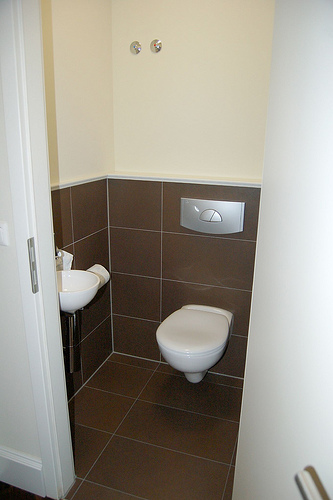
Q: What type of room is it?
A: It is a bathroom.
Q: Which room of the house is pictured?
A: It is a bathroom.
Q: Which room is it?
A: It is a bathroom.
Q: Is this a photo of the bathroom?
A: Yes, it is showing the bathroom.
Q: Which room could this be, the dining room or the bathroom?
A: It is the bathroom.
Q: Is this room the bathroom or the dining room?
A: It is the bathroom.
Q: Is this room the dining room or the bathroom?
A: It is the bathroom.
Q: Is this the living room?
A: No, it is the bathroom.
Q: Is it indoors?
A: Yes, it is indoors.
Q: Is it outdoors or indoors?
A: It is indoors.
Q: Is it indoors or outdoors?
A: It is indoors.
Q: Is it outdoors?
A: No, it is indoors.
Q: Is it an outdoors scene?
A: No, it is indoors.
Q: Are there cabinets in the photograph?
A: No, there are no cabinets.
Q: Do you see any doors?
A: Yes, there is a door.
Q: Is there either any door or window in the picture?
A: Yes, there is a door.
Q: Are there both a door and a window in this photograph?
A: No, there is a door but no windows.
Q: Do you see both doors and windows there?
A: No, there is a door but no windows.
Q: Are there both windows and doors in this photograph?
A: No, there is a door but no windows.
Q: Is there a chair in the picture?
A: No, there are no chairs.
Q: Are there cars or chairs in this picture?
A: No, there are no chairs or cars.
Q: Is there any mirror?
A: No, there are no mirrors.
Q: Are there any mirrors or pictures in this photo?
A: No, there are no mirrors or pictures.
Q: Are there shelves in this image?
A: No, there are no shelves.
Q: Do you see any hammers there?
A: No, there are no hammers.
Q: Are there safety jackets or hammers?
A: No, there are no hammers or safety jackets.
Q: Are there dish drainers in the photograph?
A: No, there are no dish drainers.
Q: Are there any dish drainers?
A: No, there are no dish drainers.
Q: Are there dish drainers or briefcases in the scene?
A: No, there are no dish drainers or briefcases.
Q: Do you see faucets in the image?
A: No, there are no faucets.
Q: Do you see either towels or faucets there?
A: No, there are no faucets or towels.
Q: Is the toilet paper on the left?
A: Yes, the toilet paper is on the left of the image.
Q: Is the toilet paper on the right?
A: No, the toilet paper is on the left of the image.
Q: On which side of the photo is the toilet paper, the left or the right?
A: The toilet paper is on the left of the image.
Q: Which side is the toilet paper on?
A: The toilet paper is on the left of the image.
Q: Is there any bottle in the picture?
A: No, there are no bottles.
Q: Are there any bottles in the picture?
A: No, there are no bottles.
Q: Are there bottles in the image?
A: No, there are no bottles.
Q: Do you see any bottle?
A: No, there are no bottles.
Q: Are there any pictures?
A: No, there are no pictures.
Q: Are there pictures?
A: No, there are no pictures.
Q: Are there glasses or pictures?
A: No, there are no pictures or glasses.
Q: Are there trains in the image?
A: Yes, there is a train.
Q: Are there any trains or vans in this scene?
A: Yes, there is a train.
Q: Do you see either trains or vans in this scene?
A: Yes, there is a train.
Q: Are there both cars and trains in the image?
A: No, there is a train but no cars.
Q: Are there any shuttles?
A: No, there are no shuttles.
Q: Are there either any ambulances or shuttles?
A: No, there are no shuttles or ambulances.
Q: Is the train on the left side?
A: Yes, the train is on the left of the image.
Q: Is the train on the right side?
A: No, the train is on the left of the image.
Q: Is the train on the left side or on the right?
A: The train is on the left of the image.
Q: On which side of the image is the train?
A: The train is on the left of the image.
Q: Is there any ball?
A: No, there are no balls.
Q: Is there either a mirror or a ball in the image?
A: No, there are no balls or mirrors.